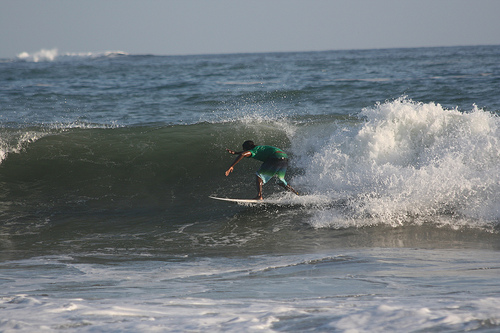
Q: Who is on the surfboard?
A: Surfer.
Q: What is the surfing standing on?
A: Surfboard.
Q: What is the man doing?
A: Surfing.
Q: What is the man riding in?
A: Wave.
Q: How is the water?
A: Rough.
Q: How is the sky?
A: Clear.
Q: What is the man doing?
A: Surfing.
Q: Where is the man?
A: At the ocean.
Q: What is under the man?
A: A surfboard.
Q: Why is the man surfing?
A: For exercise.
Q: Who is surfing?
A: The man.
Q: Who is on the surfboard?
A: The surfer.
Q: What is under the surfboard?
A: Water.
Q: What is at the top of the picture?
A: The sky.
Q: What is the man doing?
A: Surfing.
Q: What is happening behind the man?
A: The wave is crashing.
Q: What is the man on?
A: A surfboard.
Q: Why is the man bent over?
A: The wave is curling over him.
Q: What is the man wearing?
A: Shirt and shorts.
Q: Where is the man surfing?
A: In the ocean.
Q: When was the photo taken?
A: Daytime.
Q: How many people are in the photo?
A: One.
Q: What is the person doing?
A: Surfing.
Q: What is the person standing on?
A: Surfboard.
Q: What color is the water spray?
A: White.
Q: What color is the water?
A: Blue.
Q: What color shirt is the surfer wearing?
A: Green.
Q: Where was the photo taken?
A: At the beach.